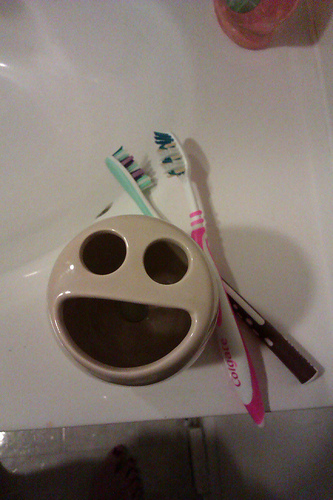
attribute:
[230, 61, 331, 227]
sink — white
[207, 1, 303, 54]
bottle — soap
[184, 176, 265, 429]
handle — purple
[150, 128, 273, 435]
toothbrush — Pink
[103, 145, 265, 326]
toothbrush — pale, green, white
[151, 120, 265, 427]
toothbrush — white, Pink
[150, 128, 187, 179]
bristles — blue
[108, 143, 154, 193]
bristles — blue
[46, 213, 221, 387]
holder — ceramic, smiling, resembles smiley face, toothbrush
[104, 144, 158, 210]
brush — green, purple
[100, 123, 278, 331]
toothbrush — pink, white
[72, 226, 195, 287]
holes — circular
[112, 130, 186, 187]
bristles — white, green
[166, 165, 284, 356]
toothbrush — Pink, white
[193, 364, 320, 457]
counter — smooth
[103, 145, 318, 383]
toothbrush — Pink, white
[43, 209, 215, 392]
cup — tan